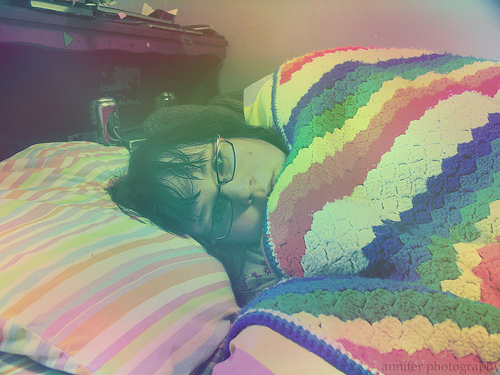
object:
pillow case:
[1, 135, 246, 373]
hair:
[156, 114, 274, 147]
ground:
[409, 110, 454, 146]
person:
[117, 95, 500, 293]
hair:
[145, 143, 198, 219]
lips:
[263, 173, 275, 197]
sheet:
[238, 47, 497, 371]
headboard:
[0, 12, 225, 161]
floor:
[210, 155, 242, 169]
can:
[90, 95, 130, 142]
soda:
[83, 99, 128, 155]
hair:
[106, 151, 158, 217]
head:
[99, 101, 299, 262]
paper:
[21, 0, 100, 16]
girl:
[105, 89, 325, 311]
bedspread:
[259, 45, 498, 372]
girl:
[105, 71, 500, 301]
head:
[106, 113, 294, 245]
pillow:
[0, 138, 243, 375]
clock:
[119, 128, 164, 157]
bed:
[2, 0, 497, 374]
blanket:
[243, 46, 498, 373]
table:
[0, 0, 227, 148]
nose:
[224, 176, 256, 208]